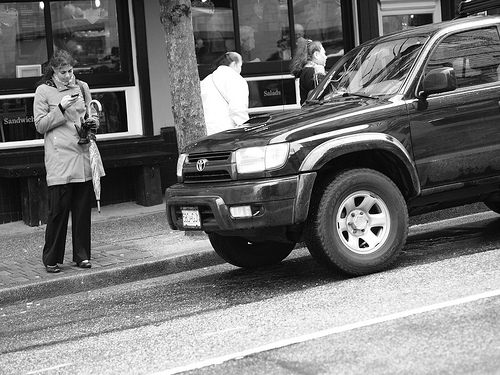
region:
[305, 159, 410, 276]
the tire on the car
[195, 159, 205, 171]
the logo on the car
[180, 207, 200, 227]
the license plate on the car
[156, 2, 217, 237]
the tree next to the car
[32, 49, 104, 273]
the woman on the sidewalk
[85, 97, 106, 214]
the umbrella in the woman's hand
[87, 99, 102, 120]
the handle for the umbrella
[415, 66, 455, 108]
the mirror on the driver's side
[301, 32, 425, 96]
the windshield on the car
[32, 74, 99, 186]
the long coat on the woman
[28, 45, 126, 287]
The woman is holding a cell phone.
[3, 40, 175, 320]
The woman is looking at her phone.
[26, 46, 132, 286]
The woman is holding an umbrella.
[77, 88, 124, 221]
The umbrella is closed.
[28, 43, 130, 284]
The woman is wearing a glove on her left hand.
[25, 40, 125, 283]
The woman is holding a glove in her left hand.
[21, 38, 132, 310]
The woman is wearing a coat.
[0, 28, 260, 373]
Thw woman is standing near the street.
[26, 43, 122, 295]
The woman is wearing pants.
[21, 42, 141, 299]
The woman is wearing shoes.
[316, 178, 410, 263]
the left front tire of the car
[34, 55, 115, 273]
a woman on the sidewalk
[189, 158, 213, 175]
Toyota logo on the front of the car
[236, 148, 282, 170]
left front head light of the car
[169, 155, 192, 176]
right front head light of the car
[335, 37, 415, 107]
it is the windshield of the car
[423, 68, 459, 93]
side mirror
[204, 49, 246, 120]
a person dressed in white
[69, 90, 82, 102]
a black smartphone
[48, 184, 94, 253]
woman wearing black pants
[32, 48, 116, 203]
A woman on her cell phone.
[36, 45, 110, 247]
A woman carrying an umbrella.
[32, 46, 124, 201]
A woman wearing a coat.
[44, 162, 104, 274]
Black pants and black shoes.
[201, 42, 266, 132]
A woman wearing a white coat.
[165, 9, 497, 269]
A dark vehicle parked by the curb.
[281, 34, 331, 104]
The woman is wearing a black coat.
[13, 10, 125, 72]
Black store front windows.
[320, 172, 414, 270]
Silver rims on a tire.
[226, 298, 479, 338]
A line painted on the street.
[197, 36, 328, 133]
People walking on the sidewalk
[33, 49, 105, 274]
Woman standing on the sidewalk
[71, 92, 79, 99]
Cellphone in the woman's right hand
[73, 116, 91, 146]
Glove in the woman's left hand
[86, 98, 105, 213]
Umbrella on the woman's arm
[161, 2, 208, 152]
Tree on the sidewalk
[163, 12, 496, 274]
Car parked on the road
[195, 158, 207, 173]
Brand logo on the car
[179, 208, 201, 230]
Licence plate on the car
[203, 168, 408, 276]
Wheels on the car